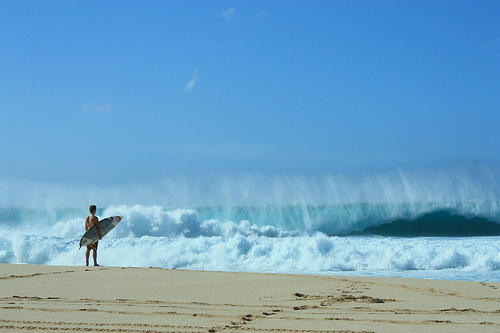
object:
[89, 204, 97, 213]
head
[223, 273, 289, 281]
dirt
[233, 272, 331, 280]
line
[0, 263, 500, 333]
ground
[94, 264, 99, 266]
foot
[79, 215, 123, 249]
surfboard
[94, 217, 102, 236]
arm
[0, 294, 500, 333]
footsteps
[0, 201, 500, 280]
ocean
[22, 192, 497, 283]
waves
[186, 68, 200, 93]
cloud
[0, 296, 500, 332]
tracks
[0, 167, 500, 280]
waves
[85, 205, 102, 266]
boy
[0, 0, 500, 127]
skies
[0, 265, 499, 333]
beach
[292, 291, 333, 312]
prints